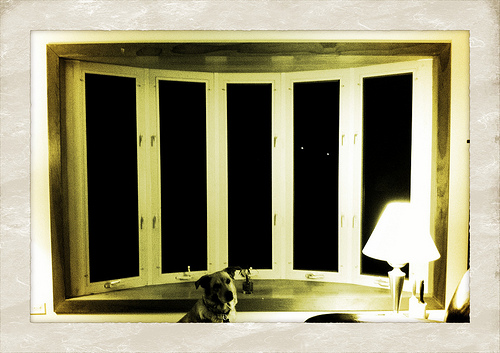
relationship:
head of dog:
[194, 268, 243, 310] [180, 266, 249, 317]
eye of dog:
[224, 273, 235, 287] [182, 265, 256, 319]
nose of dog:
[223, 290, 239, 304] [171, 264, 251, 324]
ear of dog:
[190, 271, 210, 291] [176, 264, 256, 324]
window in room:
[224, 82, 283, 276] [63, 59, 447, 302]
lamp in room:
[353, 189, 453, 321] [74, 76, 415, 297]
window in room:
[153, 80, 215, 272] [5, 3, 498, 348]